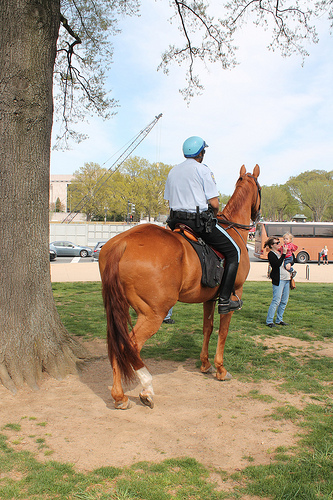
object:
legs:
[118, 308, 164, 387]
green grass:
[0, 281, 332, 497]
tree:
[1, 0, 86, 395]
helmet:
[180, 135, 206, 160]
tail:
[96, 239, 151, 388]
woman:
[262, 237, 291, 328]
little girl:
[277, 231, 298, 277]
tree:
[67, 155, 174, 225]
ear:
[239, 164, 245, 176]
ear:
[249, 163, 260, 180]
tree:
[259, 167, 332, 222]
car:
[46, 240, 92, 257]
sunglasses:
[270, 241, 278, 245]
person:
[319, 245, 328, 267]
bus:
[253, 222, 333, 261]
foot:
[217, 297, 242, 314]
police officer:
[163, 135, 244, 317]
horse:
[95, 162, 262, 411]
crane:
[57, 113, 163, 224]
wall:
[49, 220, 135, 249]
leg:
[206, 225, 241, 297]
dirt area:
[0, 333, 332, 499]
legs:
[197, 298, 216, 372]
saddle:
[172, 224, 223, 291]